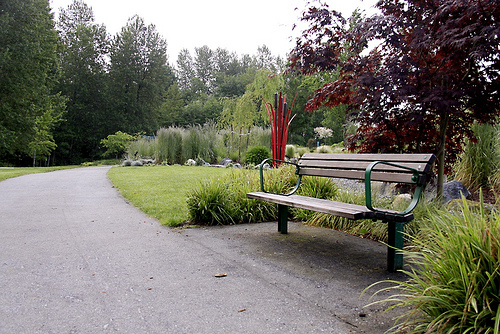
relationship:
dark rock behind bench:
[428, 180, 473, 209] [243, 138, 439, 276]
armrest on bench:
[363, 153, 428, 220] [249, 147, 434, 281]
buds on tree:
[296, 36, 481, 152] [271, 8, 498, 190]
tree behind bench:
[341, 62, 408, 142] [249, 147, 434, 281]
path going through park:
[63, 145, 390, 314] [4, 5, 498, 329]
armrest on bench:
[258, 156, 302, 196] [249, 147, 434, 281]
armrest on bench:
[363, 153, 436, 216] [249, 147, 434, 281]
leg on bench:
[246, 152, 423, 317] [243, 138, 439, 276]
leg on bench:
[386, 222, 409, 272] [249, 147, 434, 281]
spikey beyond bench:
[257, 90, 296, 170] [243, 138, 439, 276]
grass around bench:
[132, 149, 498, 331] [188, 161, 499, 331]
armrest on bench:
[258, 156, 303, 191] [249, 147, 434, 281]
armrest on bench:
[363, 153, 436, 216] [244, 149, 438, 271]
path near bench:
[0, 163, 500, 334] [247, 132, 447, 272]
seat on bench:
[245, 189, 415, 224] [244, 149, 438, 271]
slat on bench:
[296, 151, 435, 186] [249, 147, 434, 281]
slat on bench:
[246, 191, 415, 224] [237, 147, 388, 266]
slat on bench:
[246, 189, 365, 224] [244, 149, 438, 271]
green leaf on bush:
[358, 271, 410, 299] [350, 184, 499, 331]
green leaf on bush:
[358, 187, 500, 334] [350, 184, 499, 331]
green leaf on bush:
[358, 187, 500, 334] [380, 179, 497, 330]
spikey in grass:
[262, 90, 294, 177] [116, 151, 372, 230]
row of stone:
[120, 155, 284, 172] [230, 161, 242, 168]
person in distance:
[309, 129, 331, 150] [12, 112, 493, 198]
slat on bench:
[296, 156, 430, 181] [250, 128, 425, 267]